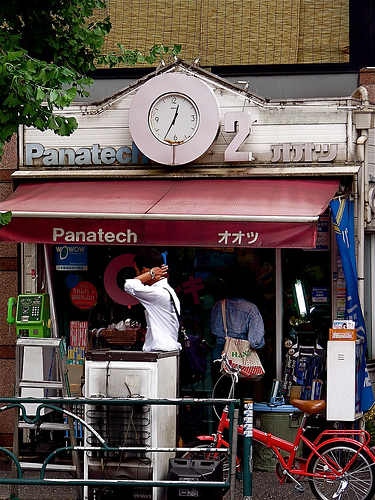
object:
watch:
[147, 270, 155, 280]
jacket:
[210, 298, 266, 351]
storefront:
[15, 60, 362, 471]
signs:
[54, 244, 88, 271]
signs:
[65, 274, 79, 289]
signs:
[70, 281, 97, 310]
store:
[1, 56, 375, 478]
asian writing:
[268, 140, 340, 165]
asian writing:
[214, 229, 261, 246]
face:
[22, 70, 349, 168]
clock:
[147, 90, 202, 147]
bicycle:
[170, 349, 375, 500]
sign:
[23, 139, 150, 167]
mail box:
[326, 334, 365, 423]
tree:
[2, 2, 184, 160]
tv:
[167, 456, 223, 498]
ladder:
[7, 333, 87, 500]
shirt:
[124, 275, 183, 352]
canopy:
[0, 170, 342, 251]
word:
[51, 226, 141, 244]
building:
[0, 1, 375, 473]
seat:
[286, 394, 326, 416]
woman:
[209, 275, 266, 400]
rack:
[312, 425, 371, 447]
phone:
[6, 292, 51, 338]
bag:
[219, 335, 265, 383]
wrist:
[146, 268, 155, 281]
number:
[171, 97, 176, 104]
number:
[190, 114, 195, 122]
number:
[173, 133, 178, 141]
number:
[155, 116, 160, 123]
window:
[47, 242, 147, 351]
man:
[124, 246, 185, 352]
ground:
[0, 465, 375, 500]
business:
[3, 64, 375, 500]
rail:
[0, 393, 243, 500]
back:
[302, 433, 375, 499]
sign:
[245, 230, 259, 245]